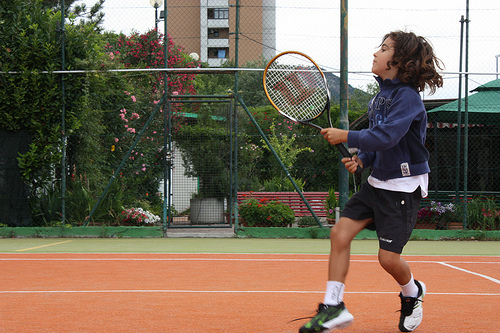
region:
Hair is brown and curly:
[379, 32, 449, 97]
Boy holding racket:
[290, 27, 442, 332]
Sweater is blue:
[345, 76, 430, 177]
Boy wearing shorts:
[291, 29, 444, 330]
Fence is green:
[0, 0, 495, 234]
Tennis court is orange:
[0, 252, 498, 332]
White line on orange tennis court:
[0, 286, 497, 296]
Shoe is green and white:
[294, 300, 353, 328]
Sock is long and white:
[322, 270, 347, 311]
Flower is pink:
[132, 97, 137, 103]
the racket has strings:
[194, 22, 357, 195]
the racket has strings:
[240, 53, 345, 255]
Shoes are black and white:
[395, 292, 430, 324]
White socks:
[324, 281, 344, 303]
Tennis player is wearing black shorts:
[361, 186, 409, 236]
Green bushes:
[32, 29, 99, 124]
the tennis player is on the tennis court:
[111, 254, 308, 331]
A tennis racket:
[261, 59, 343, 121]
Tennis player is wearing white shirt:
[392, 181, 412, 193]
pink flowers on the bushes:
[120, 113, 135, 132]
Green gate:
[178, 103, 242, 214]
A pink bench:
[286, 196, 323, 219]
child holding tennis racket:
[255, 9, 453, 303]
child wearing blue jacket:
[345, 50, 438, 182]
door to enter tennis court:
[153, 89, 243, 237]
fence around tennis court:
[81, 89, 146, 184]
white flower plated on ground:
[145, 211, 158, 225]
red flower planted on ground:
[121, 205, 145, 220]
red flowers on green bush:
[241, 190, 291, 215]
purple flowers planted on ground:
[432, 196, 457, 220]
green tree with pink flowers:
[100, 53, 166, 180]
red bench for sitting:
[247, 190, 329, 213]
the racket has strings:
[251, 61, 293, 88]